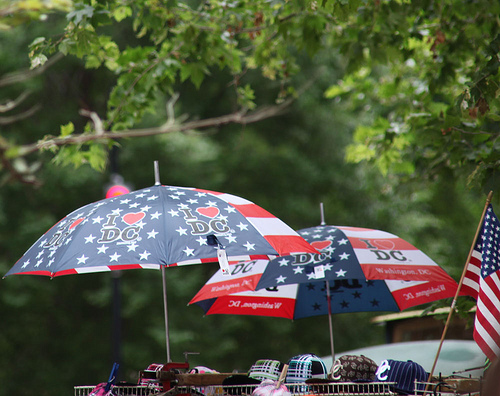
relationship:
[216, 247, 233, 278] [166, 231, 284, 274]
price tag on side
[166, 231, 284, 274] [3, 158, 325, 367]
side of umbrellas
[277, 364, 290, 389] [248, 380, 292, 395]
clothes pin holds hat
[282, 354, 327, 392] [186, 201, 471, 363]
hat under umbrella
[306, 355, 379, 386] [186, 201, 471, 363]
hat under umbrella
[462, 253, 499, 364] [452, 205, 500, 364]
stripes are on flag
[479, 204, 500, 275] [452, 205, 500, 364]
stars are on flag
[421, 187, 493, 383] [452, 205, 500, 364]
stick attached to flag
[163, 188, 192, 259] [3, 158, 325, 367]
stars are on umbrellas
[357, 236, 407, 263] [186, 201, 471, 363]
i love dc on umbrella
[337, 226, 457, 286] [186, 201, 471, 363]
stripes are on umbrella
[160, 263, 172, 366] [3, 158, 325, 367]
pole on umbrellas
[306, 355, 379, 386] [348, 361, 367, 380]
hat with designs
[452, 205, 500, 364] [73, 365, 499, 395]
flag in cart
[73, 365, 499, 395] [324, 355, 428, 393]
cart holding hats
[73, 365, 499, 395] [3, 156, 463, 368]
cart holding umbrellas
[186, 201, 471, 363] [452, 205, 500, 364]
umbrella next to flag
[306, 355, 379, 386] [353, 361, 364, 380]
hat has print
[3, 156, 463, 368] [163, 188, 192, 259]
umbrellas have stars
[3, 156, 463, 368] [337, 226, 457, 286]
umbrellas have stripes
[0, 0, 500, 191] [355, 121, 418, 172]
trees with leaves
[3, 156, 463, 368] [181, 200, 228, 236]
umbrellas say i love dc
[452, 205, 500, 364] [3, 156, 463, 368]
flag next to umbrellas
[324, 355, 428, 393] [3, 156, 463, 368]
hats are in front of umbrellas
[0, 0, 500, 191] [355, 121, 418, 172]
trees have leaves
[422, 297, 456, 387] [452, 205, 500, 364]
handle on flag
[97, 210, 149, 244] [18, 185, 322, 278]
i love dc written on item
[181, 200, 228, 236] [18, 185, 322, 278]
i love dc written on item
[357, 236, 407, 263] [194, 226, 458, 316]
i love dc written on item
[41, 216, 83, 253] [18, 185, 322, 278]
i love dc written on item